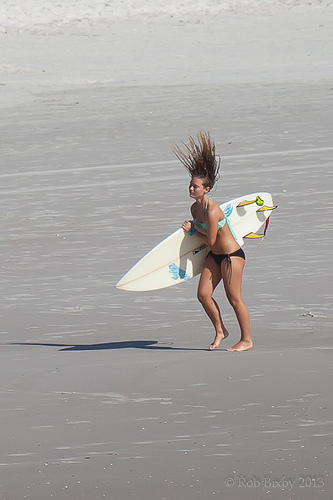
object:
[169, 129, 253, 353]
girl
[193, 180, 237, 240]
top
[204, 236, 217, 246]
elbow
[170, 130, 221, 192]
hair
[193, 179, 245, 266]
swim suit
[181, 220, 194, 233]
hand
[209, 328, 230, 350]
foot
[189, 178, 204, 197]
face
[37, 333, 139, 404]
sand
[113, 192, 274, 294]
surfboard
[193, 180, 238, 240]
bikini top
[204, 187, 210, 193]
ear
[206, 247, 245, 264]
bikini bottoms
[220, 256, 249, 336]
legs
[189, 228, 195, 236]
wristband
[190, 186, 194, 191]
nose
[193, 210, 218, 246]
arm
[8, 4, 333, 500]
beach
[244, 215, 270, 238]
strap